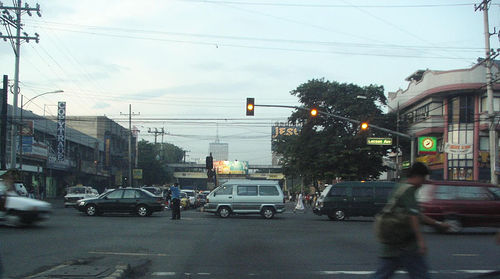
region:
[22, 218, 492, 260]
street for vehicles to travel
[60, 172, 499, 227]
vehicles on the street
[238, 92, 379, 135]
lights hanging over street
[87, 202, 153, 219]
wheels on the vehicle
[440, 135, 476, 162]
banner hanging off building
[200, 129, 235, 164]
building in the distance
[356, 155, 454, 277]
person crossing the street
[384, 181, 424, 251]
shirt on the person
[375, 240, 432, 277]
pants on the person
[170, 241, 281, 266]
the road is tarmacked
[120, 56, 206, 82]
this is the sky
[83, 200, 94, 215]
this is the wheel of the car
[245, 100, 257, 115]
this is a traffic light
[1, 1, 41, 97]
this is an electric pole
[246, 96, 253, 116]
the traffic light is yellow in colour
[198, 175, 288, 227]
the van is silver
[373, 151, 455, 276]
man is crossing the road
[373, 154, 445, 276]
man has a backpack on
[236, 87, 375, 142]
the yellow lights are on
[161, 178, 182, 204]
the shirt is blue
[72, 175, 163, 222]
the car is black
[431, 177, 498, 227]
the car is blurred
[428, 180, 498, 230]
the car is red in color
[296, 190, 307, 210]
the man is in white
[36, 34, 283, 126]
electrical wires are in the air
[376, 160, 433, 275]
a guy with his backpack hanging in his shoulder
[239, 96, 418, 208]
a traffic signal is signalling the vehicles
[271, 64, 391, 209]
the tree with green leaves in its branches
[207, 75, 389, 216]
a well grown tree on the road side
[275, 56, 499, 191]
there is a tree beside the building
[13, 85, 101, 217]
street lamp on the side of the road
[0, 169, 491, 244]
busy traffic on the road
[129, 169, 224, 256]
people standing in the middle of the road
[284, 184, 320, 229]
a person in white dress is walking on the road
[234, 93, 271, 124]
yellow street light on pole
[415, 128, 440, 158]
sign for a food place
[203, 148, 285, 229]
old small compact van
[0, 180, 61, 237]
car motion blurred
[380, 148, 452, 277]
person walking across a street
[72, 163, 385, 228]
traffic and a man waiting to cross a street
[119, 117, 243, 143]
power line in the sky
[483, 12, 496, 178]
power rod for electricity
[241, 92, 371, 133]
three yellow lights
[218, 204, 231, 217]
the vehicles front tire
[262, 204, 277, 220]
the vehicles rear tire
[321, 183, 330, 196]
the front windshield of the vehicle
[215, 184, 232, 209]
the sidedoor of the vehicle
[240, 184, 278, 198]
the rear windows of the vehicle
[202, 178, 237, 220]
the front of the vehicle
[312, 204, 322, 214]
the vehicles bumper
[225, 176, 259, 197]
the vehicles side window above door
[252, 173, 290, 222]
the rear part of the vehicle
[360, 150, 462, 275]
a man crossing a street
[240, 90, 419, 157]
three traffic lights on a pole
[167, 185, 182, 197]
a person wearing a blue shirt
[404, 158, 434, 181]
a person wearing a black hat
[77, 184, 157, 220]
a black car with four doors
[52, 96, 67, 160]
a blue sign with white letters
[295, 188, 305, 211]
a person wearing a white dress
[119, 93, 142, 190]
a wood electrical pole